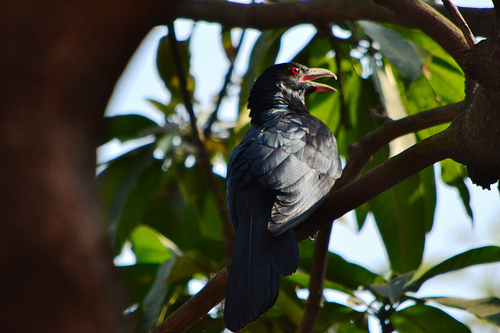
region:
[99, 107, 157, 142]
a green tree leaf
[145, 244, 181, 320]
a green tree leaf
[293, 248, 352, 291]
a green tree leaf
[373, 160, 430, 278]
a green tree leaf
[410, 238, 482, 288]
a green tree leaf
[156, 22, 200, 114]
a green tree leaf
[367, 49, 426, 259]
a green tree leaf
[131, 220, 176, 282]
a green tree leaf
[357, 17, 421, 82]
a green tree leaf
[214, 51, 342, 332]
The black bird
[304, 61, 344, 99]
The black bird's beak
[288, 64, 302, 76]
The red eye of the black bird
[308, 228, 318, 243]
The foot of the black bird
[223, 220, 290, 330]
The tail of the black bird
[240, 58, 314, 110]
The head of the bird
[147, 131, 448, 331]
The branch the bird is on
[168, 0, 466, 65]
The branch above the bird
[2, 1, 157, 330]
The trunk of the tree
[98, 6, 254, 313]
The sky seen shown behind the bird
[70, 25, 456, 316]
black bird on a tree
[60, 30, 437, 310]
beautiful black bird on a tree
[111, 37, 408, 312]
attractive black bird on a tree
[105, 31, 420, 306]
pretty black bird on a tree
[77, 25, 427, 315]
alert black bird on a tree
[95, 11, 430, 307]
nice looking black bird on a tree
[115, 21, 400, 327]
healthy black bird on a tree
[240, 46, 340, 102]
head of a bird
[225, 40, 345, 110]
head of a nice black bird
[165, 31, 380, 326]
black bird sitting on a small branch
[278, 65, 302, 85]
Bird has red eye.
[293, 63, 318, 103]
Black round pupil inside red eye.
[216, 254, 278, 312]
Bird has black tail feathers.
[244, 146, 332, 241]
Bird's wing is black.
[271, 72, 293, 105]
Bird has black head.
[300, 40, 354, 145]
Bird has orange beak.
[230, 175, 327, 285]
Bird is perched on a branch.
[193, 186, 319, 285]
Branch is brown in color.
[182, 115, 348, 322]
Green leaves on tree.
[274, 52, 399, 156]
Bird's mouth is open.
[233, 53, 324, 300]
The bird is black.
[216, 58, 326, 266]
The bird is sitting in a tree.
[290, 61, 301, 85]
The bird eye is red.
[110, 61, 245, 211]
The tree has green leaves.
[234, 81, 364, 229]
The bird is sitting on a branch.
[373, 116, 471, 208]
The branch is brown.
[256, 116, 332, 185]
The bird has black feather.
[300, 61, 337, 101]
The bird's beak is open.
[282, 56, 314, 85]
Part of the bird eye is red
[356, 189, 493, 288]
The sky is blue.